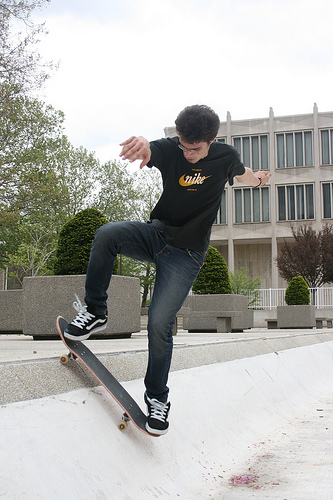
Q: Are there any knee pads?
A: No, there are no knee pads.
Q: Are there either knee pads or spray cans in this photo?
A: No, there are no knee pads or spray cans.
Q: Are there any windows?
A: Yes, there are windows.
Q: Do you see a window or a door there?
A: Yes, there are windows.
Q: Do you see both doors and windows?
A: No, there are windows but no doors.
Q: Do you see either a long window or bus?
A: Yes, there are long windows.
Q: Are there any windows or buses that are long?
A: Yes, the windows are long.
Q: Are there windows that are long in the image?
A: Yes, there are long windows.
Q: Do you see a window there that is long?
A: Yes, there are windows that are long.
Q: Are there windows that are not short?
A: Yes, there are long windows.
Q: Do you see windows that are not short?
A: Yes, there are long windows.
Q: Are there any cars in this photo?
A: No, there are no cars.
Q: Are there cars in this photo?
A: No, there are no cars.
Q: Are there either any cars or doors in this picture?
A: No, there are no cars or doors.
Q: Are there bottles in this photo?
A: No, there are no bottles.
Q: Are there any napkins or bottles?
A: No, there are no bottles or napkins.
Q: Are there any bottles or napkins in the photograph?
A: No, there are no bottles or napkins.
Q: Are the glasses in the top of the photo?
A: Yes, the glasses are in the top of the image.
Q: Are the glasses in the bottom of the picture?
A: No, the glasses are in the top of the image.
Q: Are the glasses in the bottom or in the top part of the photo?
A: The glasses are in the top of the image.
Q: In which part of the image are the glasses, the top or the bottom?
A: The glasses are in the top of the image.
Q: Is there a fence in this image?
A: Yes, there is a fence.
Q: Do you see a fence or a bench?
A: Yes, there is a fence.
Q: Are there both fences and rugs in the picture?
A: No, there is a fence but no rugs.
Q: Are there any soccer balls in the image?
A: No, there are no soccer balls.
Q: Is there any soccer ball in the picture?
A: No, there are no soccer balls.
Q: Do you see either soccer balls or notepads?
A: No, there are no soccer balls or notepads.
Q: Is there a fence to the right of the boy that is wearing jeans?
A: Yes, there is a fence to the right of the boy.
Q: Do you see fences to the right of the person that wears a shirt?
A: Yes, there is a fence to the right of the boy.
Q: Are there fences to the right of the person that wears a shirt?
A: Yes, there is a fence to the right of the boy.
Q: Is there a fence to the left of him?
A: No, the fence is to the right of the boy.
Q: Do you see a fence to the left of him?
A: No, the fence is to the right of the boy.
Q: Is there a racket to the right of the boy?
A: No, there is a fence to the right of the boy.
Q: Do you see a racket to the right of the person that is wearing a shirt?
A: No, there is a fence to the right of the boy.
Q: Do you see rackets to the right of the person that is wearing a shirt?
A: No, there is a fence to the right of the boy.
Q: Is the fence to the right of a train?
A: No, the fence is to the right of the boy.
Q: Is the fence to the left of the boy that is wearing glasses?
A: No, the fence is to the right of the boy.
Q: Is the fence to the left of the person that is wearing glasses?
A: No, the fence is to the right of the boy.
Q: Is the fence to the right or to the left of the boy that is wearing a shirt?
A: The fence is to the right of the boy.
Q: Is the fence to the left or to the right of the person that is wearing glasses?
A: The fence is to the right of the boy.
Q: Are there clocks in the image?
A: No, there are no clocks.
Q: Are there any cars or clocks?
A: No, there are no clocks or cars.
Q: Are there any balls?
A: No, there are no balls.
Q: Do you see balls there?
A: No, there are no balls.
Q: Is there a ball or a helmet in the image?
A: No, there are no balls or helmets.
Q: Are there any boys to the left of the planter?
A: Yes, there is a boy to the left of the planter.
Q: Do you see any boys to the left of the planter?
A: Yes, there is a boy to the left of the planter.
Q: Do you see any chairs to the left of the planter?
A: No, there is a boy to the left of the planter.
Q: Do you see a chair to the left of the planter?
A: No, there is a boy to the left of the planter.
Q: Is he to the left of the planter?
A: Yes, the boy is to the left of the planter.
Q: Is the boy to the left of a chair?
A: No, the boy is to the left of the planter.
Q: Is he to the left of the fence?
A: Yes, the boy is to the left of the fence.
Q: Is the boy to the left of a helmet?
A: No, the boy is to the left of the fence.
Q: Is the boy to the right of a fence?
A: No, the boy is to the left of a fence.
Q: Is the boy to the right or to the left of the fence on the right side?
A: The boy is to the left of the fence.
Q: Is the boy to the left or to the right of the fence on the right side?
A: The boy is to the left of the fence.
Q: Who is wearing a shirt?
A: The boy is wearing a shirt.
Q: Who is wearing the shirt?
A: The boy is wearing a shirt.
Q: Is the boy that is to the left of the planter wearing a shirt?
A: Yes, the boy is wearing a shirt.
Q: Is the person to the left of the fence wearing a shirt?
A: Yes, the boy is wearing a shirt.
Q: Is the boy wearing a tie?
A: No, the boy is wearing a shirt.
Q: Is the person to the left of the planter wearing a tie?
A: No, the boy is wearing a shirt.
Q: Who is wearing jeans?
A: The boy is wearing jeans.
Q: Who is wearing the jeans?
A: The boy is wearing jeans.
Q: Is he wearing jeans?
A: Yes, the boy is wearing jeans.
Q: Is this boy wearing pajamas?
A: No, the boy is wearing jeans.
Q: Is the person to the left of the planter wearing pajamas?
A: No, the boy is wearing jeans.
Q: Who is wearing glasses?
A: The boy is wearing glasses.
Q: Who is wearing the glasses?
A: The boy is wearing glasses.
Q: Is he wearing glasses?
A: Yes, the boy is wearing glasses.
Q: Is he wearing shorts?
A: No, the boy is wearing glasses.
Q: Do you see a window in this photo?
A: Yes, there are windows.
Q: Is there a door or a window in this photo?
A: Yes, there are windows.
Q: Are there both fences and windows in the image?
A: Yes, there are both windows and a fence.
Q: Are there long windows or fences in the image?
A: Yes, there are long windows.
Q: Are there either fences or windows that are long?
A: Yes, the windows are long.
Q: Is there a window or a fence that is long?
A: Yes, the windows are long.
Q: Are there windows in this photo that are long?
A: Yes, there are long windows.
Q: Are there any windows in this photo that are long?
A: Yes, there are windows that are long.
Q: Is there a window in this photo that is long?
A: Yes, there are windows that are long.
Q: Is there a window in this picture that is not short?
A: Yes, there are long windows.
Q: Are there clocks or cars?
A: No, there are no cars or clocks.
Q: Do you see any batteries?
A: No, there are no batteries.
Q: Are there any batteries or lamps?
A: No, there are no batteries or lamps.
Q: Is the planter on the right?
A: Yes, the planter is on the right of the image.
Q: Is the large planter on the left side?
A: No, the planter is on the right of the image.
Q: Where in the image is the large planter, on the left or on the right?
A: The planter is on the right of the image.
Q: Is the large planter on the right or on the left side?
A: The planter is on the right of the image.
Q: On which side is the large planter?
A: The planter is on the right of the image.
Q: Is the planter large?
A: Yes, the planter is large.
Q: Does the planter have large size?
A: Yes, the planter is large.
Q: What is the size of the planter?
A: The planter is large.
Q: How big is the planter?
A: The planter is large.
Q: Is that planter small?
A: No, the planter is large.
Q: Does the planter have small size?
A: No, the planter is large.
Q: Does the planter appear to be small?
A: No, the planter is large.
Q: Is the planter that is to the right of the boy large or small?
A: The planter is large.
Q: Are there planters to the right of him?
A: Yes, there is a planter to the right of the boy.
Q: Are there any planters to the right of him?
A: Yes, there is a planter to the right of the boy.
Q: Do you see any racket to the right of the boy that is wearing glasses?
A: No, there is a planter to the right of the boy.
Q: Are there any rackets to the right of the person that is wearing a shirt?
A: No, there is a planter to the right of the boy.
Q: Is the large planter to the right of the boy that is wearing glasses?
A: Yes, the planter is to the right of the boy.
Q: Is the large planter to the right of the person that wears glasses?
A: Yes, the planter is to the right of the boy.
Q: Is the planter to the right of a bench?
A: No, the planter is to the right of the boy.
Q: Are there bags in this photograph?
A: No, there are no bags.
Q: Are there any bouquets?
A: No, there are no bouquets.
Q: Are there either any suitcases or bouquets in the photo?
A: No, there are no bouquets or suitcases.